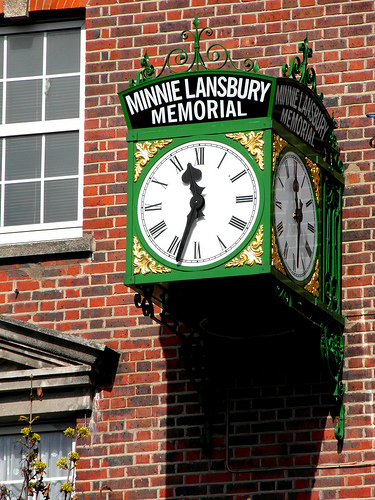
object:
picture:
[0, 5, 375, 491]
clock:
[130, 133, 261, 272]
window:
[1, 10, 84, 245]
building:
[0, 0, 375, 500]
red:
[91, 10, 135, 32]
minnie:
[125, 80, 183, 115]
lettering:
[125, 89, 144, 115]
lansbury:
[182, 77, 270, 101]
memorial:
[150, 99, 247, 125]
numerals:
[235, 195, 252, 203]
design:
[221, 129, 267, 171]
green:
[122, 258, 273, 287]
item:
[116, 16, 351, 421]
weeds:
[0, 368, 89, 500]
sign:
[116, 70, 268, 122]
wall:
[88, 3, 132, 84]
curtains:
[1, 434, 73, 500]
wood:
[0, 116, 81, 138]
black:
[175, 205, 198, 265]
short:
[181, 163, 207, 210]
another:
[274, 153, 321, 280]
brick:
[110, 27, 141, 38]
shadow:
[160, 309, 327, 491]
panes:
[5, 36, 42, 76]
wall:
[1, 3, 108, 500]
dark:
[94, 6, 125, 240]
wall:
[116, 11, 348, 293]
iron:
[127, 15, 314, 81]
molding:
[0, 315, 118, 414]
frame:
[116, 13, 344, 447]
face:
[134, 138, 262, 270]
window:
[0, 425, 77, 497]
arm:
[176, 207, 200, 266]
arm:
[179, 161, 206, 193]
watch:
[272, 121, 319, 295]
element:
[21, 382, 89, 493]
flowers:
[57, 424, 89, 487]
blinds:
[3, 23, 78, 246]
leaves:
[225, 128, 263, 171]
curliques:
[129, 20, 258, 84]